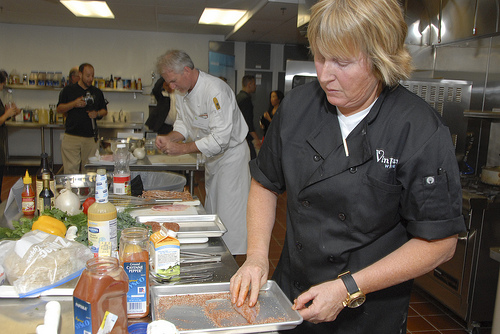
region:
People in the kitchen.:
[45, 34, 417, 329]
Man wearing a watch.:
[305, 248, 383, 319]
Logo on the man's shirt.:
[320, 100, 421, 170]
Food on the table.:
[11, 135, 246, 332]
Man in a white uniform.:
[138, 47, 290, 254]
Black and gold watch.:
[320, 252, 395, 332]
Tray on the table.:
[164, 244, 291, 332]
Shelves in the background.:
[20, 52, 118, 167]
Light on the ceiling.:
[60, 4, 152, 41]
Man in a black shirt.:
[53, 45, 162, 209]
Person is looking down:
[271, 2, 442, 119]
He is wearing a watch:
[332, 267, 382, 311]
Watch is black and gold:
[332, 267, 374, 316]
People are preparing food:
[127, 10, 491, 332]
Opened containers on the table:
[59, 219, 174, 331]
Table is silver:
[16, 161, 288, 332]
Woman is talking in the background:
[260, 82, 288, 109]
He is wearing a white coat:
[151, 48, 271, 263]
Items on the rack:
[2, 57, 166, 135]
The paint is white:
[57, 26, 138, 61]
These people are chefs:
[120, 40, 440, 270]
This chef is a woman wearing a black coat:
[281, 12, 450, 280]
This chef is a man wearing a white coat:
[150, 44, 242, 158]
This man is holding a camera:
[57, 55, 114, 142]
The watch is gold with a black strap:
[334, 264, 372, 312]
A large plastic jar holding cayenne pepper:
[124, 233, 149, 322]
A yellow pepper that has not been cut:
[29, 209, 70, 241]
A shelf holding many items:
[22, 68, 138, 88]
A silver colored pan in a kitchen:
[140, 277, 300, 326]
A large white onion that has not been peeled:
[53, 182, 85, 221]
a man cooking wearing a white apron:
[135, 44, 270, 256]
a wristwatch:
[327, 267, 369, 309]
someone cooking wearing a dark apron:
[232, 2, 468, 319]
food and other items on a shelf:
[7, 62, 147, 98]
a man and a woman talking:
[235, 69, 291, 130]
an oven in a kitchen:
[421, 188, 491, 313]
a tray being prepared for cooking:
[148, 280, 305, 330]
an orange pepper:
[25, 209, 74, 246]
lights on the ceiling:
[190, 2, 253, 43]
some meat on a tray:
[131, 209, 228, 246]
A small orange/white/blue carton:
[145, 217, 190, 277]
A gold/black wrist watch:
[330, 265, 370, 315]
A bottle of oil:
[100, 130, 135, 195]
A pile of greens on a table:
[0, 205, 155, 245]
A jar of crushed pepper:
[105, 220, 165, 320]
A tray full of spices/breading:
[140, 275, 300, 330]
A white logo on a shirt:
[420, 171, 437, 182]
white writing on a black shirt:
[366, 145, 396, 170]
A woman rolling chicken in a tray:
[220, 0, 465, 330]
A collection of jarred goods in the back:
[21, 60, 66, 90]